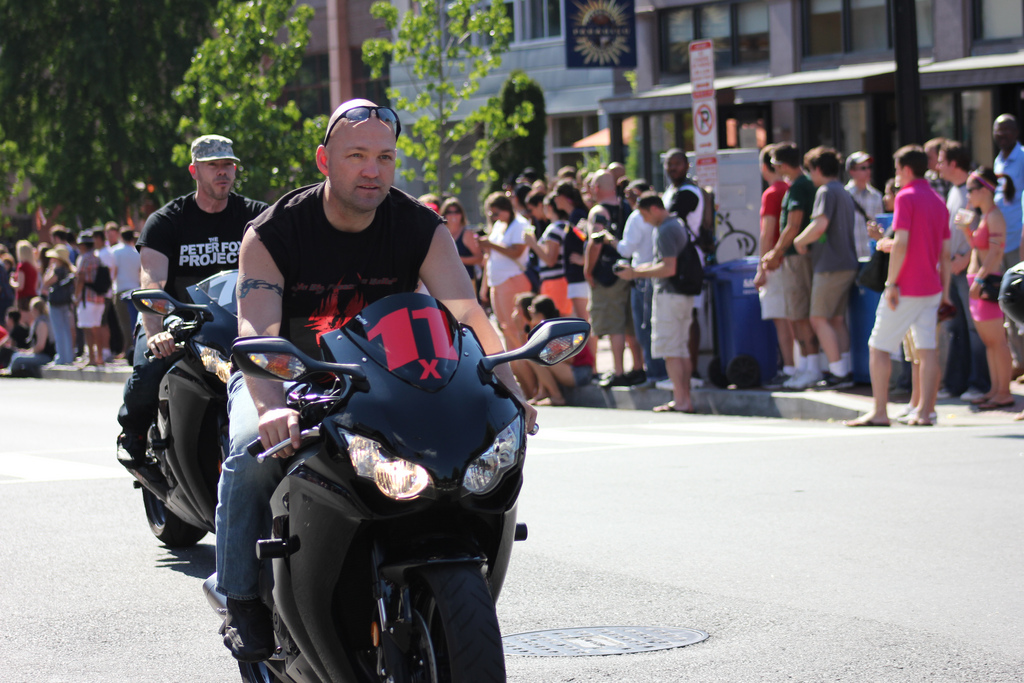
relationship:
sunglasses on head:
[319, 98, 408, 138] [302, 96, 409, 218]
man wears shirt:
[840, 143, 959, 433] [877, 176, 962, 297]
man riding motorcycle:
[211, 98, 536, 664] [209, 290, 605, 679]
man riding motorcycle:
[108, 126, 283, 509] [97, 264, 290, 565]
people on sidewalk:
[488, 111, 990, 397] [592, 368, 990, 436]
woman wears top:
[460, 182, 556, 405] [475, 215, 543, 293]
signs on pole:
[682, 33, 726, 194] [691, 191, 724, 390]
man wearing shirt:
[611, 186, 711, 422] [648, 204, 688, 291]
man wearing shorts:
[840, 143, 959, 433] [851, 286, 949, 360]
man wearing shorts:
[611, 186, 711, 422] [639, 288, 702, 368]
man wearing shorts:
[743, 141, 810, 386] [749, 253, 801, 327]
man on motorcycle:
[211, 98, 536, 664] [209, 290, 605, 679]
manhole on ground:
[490, 608, 724, 671] [6, 381, 989, 677]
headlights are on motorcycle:
[330, 424, 542, 500] [227, 344, 506, 677]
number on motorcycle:
[375, 297, 462, 377] [253, 338, 541, 678]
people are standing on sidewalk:
[531, 161, 700, 367] [741, 381, 865, 425]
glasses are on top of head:
[343, 100, 396, 131] [315, 98, 406, 217]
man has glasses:
[235, 89, 475, 332] [343, 100, 396, 131]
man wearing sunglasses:
[211, 98, 536, 664] [325, 105, 404, 146]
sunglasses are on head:
[325, 105, 404, 146] [319, 96, 410, 209]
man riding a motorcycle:
[211, 98, 536, 664] [283, 310, 532, 676]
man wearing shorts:
[843, 146, 953, 427] [873, 286, 951, 349]